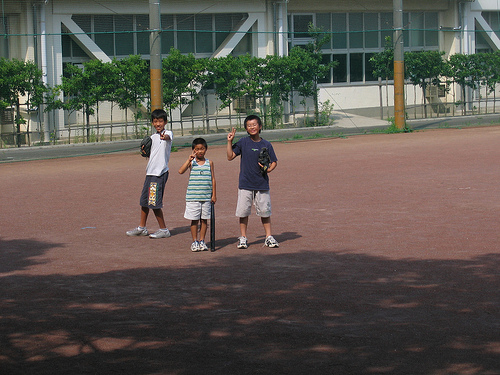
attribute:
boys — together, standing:
[124, 108, 281, 253]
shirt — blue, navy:
[231, 133, 279, 192]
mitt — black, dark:
[139, 133, 154, 161]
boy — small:
[179, 137, 220, 255]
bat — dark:
[208, 196, 216, 255]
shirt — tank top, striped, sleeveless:
[185, 156, 213, 204]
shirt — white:
[145, 129, 174, 179]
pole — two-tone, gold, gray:
[147, 1, 164, 140]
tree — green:
[0, 56, 49, 151]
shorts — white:
[183, 199, 215, 221]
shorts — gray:
[234, 188, 275, 220]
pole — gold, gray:
[390, 0, 409, 136]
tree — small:
[404, 48, 453, 122]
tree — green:
[45, 54, 132, 146]